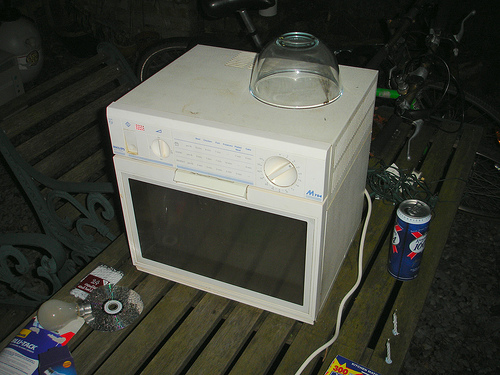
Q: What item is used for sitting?
A: A bench.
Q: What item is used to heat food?
A: A microwave.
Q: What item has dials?
A: A microwave.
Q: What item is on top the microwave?
A: A clear bowl.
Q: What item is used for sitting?
A: A bench.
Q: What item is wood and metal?
A: The bench.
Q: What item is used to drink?
A: A soda.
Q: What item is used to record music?
A: A CD.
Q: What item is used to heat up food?
A: A microwave.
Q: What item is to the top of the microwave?
A: A bowl.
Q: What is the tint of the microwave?
A: White.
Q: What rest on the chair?
A: A metal arm.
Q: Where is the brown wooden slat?
A: On the table.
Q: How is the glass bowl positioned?
A: Upside down.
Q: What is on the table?
A: A white microwave.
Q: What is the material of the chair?
A: Metal and wooden.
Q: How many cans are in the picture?
A: One.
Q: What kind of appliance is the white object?
A: Microwave.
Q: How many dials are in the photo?
A: Two.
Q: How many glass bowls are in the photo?
A: One.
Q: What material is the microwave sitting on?
A: Wood.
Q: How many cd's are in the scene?
A: One.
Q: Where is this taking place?
A: On an outside porch of a home.